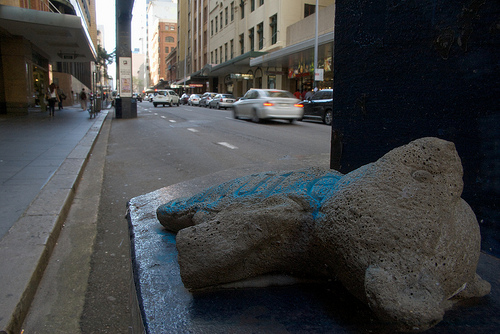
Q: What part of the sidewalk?
A: Curb.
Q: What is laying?
A: The bear.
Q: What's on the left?
A: A curb.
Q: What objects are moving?
A: Vehicles.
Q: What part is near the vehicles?
A: A building.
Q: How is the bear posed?
A: Laying.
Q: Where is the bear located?
A: In the street.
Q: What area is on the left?
A: A building.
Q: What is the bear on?
A: A platform.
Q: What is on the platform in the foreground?
A: A dirty teddy bear.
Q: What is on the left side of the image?
A: A sidewalk.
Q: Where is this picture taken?
A: On a city street.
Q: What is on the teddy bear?
A: Spray paint.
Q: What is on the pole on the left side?
A: A sign.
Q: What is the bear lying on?
A: A blue platform.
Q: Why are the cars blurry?
A: Out of focus.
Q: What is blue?
A: The markings on the bear.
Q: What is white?
A: Car.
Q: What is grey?
A: Light pole on right.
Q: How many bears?
A: One.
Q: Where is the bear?
A: On a truck.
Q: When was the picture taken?
A: Daytime.